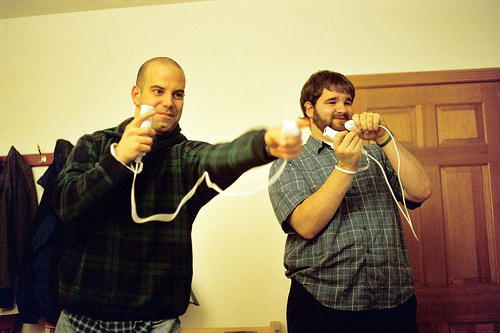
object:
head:
[299, 70, 356, 136]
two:
[49, 57, 434, 333]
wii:
[320, 117, 422, 244]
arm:
[268, 159, 356, 239]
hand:
[331, 129, 362, 175]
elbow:
[407, 182, 432, 200]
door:
[342, 66, 500, 333]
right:
[285, 0, 500, 333]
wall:
[0, 0, 500, 333]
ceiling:
[0, 0, 191, 19]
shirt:
[51, 116, 278, 322]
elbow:
[289, 217, 323, 240]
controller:
[321, 123, 369, 166]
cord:
[361, 124, 422, 244]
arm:
[180, 128, 268, 207]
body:
[46, 116, 303, 332]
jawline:
[326, 120, 347, 134]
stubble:
[135, 55, 187, 96]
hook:
[35, 143, 45, 164]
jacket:
[0, 146, 40, 313]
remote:
[130, 104, 155, 165]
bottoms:
[285, 279, 420, 333]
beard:
[311, 106, 353, 134]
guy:
[266, 68, 432, 332]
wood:
[340, 66, 499, 90]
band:
[376, 131, 395, 149]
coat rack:
[0, 153, 56, 169]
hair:
[298, 69, 357, 120]